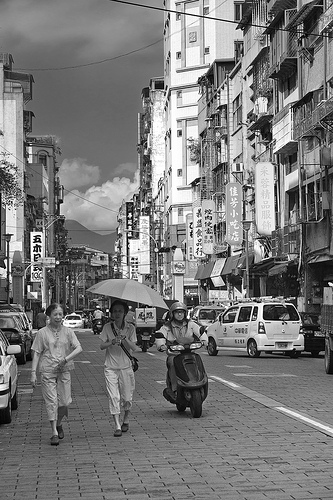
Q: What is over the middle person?
A: An umbrella.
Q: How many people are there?
A: Three.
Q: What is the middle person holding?
A: The umbrella.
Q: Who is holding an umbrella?
A: The person in the middle.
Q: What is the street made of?
A: Stone.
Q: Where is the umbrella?
A: Over the middle person's head.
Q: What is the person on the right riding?
A: A moped.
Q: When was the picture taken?
A: Daytime.